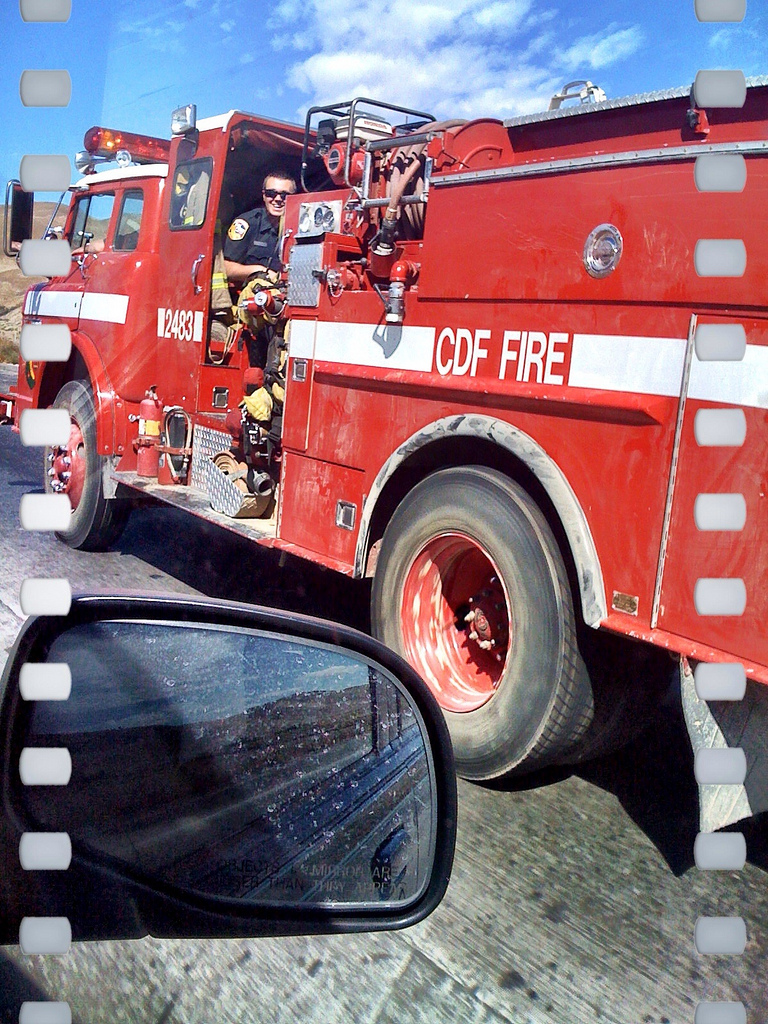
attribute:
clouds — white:
[238, 6, 564, 119]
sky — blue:
[25, 12, 714, 144]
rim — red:
[402, 527, 522, 707]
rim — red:
[41, 416, 89, 501]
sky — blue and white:
[164, 8, 494, 108]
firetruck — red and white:
[32, 121, 727, 753]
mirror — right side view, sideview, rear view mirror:
[22, 587, 470, 950]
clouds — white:
[139, 16, 633, 134]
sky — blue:
[55, 29, 683, 100]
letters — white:
[418, 335, 582, 402]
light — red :
[57, 75, 193, 169]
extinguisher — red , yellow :
[117, 361, 207, 509]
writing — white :
[387, 280, 597, 401]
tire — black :
[390, 490, 584, 762]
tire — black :
[374, 414, 615, 802]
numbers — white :
[129, 277, 239, 388]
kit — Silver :
[184, 370, 334, 624]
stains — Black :
[468, 916, 599, 1008]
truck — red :
[78, 113, 656, 769]